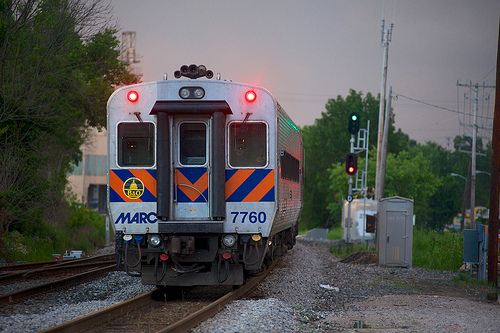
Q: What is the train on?
A: Track.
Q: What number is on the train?
A: 7760.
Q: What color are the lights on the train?
A: Red.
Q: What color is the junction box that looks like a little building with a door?
A: Gray.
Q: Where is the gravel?
A: Along the tracks.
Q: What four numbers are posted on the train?
A: 7760.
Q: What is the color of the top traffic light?
A: Green.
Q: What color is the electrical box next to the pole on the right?
A: Blue.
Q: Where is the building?
A: The background.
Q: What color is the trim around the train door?
A: Black.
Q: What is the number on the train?
A: 7760.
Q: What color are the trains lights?
A: Red.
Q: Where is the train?
A: An intersection.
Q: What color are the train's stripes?
A: Orange and blue.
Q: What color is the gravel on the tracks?
A: Grey.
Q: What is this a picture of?
A: A train.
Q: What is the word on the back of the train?
A: Marc.